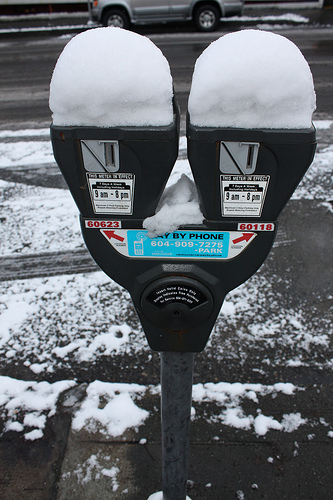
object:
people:
[14, 49, 48, 98]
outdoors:
[0, 0, 333, 499]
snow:
[50, 28, 176, 126]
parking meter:
[47, 26, 316, 353]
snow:
[189, 29, 315, 130]